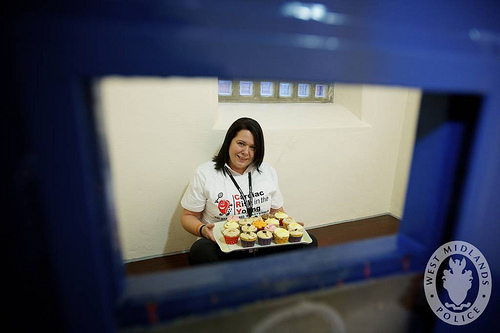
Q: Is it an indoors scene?
A: Yes, it is indoors.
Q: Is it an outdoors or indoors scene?
A: It is indoors.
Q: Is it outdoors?
A: No, it is indoors.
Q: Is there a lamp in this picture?
A: No, there are no lamps.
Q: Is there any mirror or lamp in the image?
A: No, there are no lamps or mirrors.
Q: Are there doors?
A: Yes, there is a door.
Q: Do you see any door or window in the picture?
A: Yes, there is a door.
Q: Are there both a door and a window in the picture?
A: Yes, there are both a door and a window.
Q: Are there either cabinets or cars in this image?
A: No, there are no cars or cabinets.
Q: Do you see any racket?
A: No, there are no rackets.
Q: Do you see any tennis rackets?
A: No, there are no tennis rackets.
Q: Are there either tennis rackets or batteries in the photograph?
A: No, there are no tennis rackets or batteries.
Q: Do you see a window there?
A: Yes, there is a window.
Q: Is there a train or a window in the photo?
A: Yes, there is a window.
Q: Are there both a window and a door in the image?
A: Yes, there are both a window and a door.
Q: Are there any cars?
A: No, there are no cars.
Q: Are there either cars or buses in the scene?
A: No, there are no cars or buses.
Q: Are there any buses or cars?
A: No, there are no cars or buses.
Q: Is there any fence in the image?
A: No, there are no fences.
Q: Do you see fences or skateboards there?
A: No, there are no fences or skateboards.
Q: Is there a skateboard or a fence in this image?
A: No, there are no fences or skateboards.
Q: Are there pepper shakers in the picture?
A: No, there are no pepper shakers.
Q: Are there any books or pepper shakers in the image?
A: No, there are no pepper shakers or books.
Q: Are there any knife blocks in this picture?
A: No, there are no knife blocks.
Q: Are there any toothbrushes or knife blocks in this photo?
A: No, there are no knife blocks or toothbrushes.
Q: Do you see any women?
A: Yes, there is a woman.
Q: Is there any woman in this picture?
A: Yes, there is a woman.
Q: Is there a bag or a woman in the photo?
A: Yes, there is a woman.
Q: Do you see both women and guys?
A: No, there is a woman but no guys.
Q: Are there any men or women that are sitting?
A: Yes, the woman is sitting.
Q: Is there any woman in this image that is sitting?
A: Yes, there is a woman that is sitting.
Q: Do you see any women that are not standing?
A: Yes, there is a woman that is sitting .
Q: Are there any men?
A: No, there are no men.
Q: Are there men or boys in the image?
A: No, there are no men or boys.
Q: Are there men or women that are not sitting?
A: No, there is a woman but she is sitting.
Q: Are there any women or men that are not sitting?
A: No, there is a woman but she is sitting.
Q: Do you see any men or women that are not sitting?
A: No, there is a woman but she is sitting.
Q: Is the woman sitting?
A: Yes, the woman is sitting.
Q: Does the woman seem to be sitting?
A: Yes, the woman is sitting.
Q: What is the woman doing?
A: The woman is sitting.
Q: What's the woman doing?
A: The woman is sitting.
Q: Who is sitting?
A: The woman is sitting.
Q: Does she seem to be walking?
A: No, the woman is sitting.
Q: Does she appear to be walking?
A: No, the woman is sitting.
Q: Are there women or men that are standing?
A: No, there is a woman but she is sitting.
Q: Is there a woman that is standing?
A: No, there is a woman but she is sitting.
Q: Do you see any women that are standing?
A: No, there is a woman but she is sitting.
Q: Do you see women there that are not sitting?
A: No, there is a woman but she is sitting.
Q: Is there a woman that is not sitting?
A: No, there is a woman but she is sitting.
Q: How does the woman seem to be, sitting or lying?
A: The woman is sitting.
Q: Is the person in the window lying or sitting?
A: The woman is sitting.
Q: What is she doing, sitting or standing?
A: The woman is sitting.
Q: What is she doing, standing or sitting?
A: The woman is sitting.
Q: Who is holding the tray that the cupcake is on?
A: The woman is holding the tray.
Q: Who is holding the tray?
A: The woman is holding the tray.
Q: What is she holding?
A: The woman is holding the tray.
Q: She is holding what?
A: The woman is holding the tray.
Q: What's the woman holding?
A: The woman is holding the tray.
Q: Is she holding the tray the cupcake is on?
A: Yes, the woman is holding the tray.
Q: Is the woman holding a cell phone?
A: No, the woman is holding the tray.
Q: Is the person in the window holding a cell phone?
A: No, the woman is holding the tray.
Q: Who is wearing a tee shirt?
A: The woman is wearing a tee shirt.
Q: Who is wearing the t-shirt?
A: The woman is wearing a tee shirt.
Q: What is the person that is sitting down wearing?
A: The woman is wearing a t-shirt.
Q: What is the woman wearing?
A: The woman is wearing a t-shirt.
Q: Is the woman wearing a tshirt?
A: Yes, the woman is wearing a tshirt.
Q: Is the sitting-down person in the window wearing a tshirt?
A: Yes, the woman is wearing a tshirt.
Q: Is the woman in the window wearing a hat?
A: No, the woman is wearing a tshirt.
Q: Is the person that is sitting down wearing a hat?
A: No, the woman is wearing a tshirt.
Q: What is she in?
A: The woman is in the window.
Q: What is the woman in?
A: The woman is in the window.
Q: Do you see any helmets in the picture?
A: No, there are no helmets.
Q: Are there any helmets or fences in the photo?
A: No, there are no helmets or fences.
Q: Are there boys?
A: No, there are no boys.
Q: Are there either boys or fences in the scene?
A: No, there are no boys or fences.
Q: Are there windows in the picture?
A: Yes, there is a window.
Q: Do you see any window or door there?
A: Yes, there is a window.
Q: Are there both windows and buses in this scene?
A: No, there is a window but no buses.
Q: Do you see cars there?
A: No, there are no cars.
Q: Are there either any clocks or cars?
A: No, there are no cars or clocks.